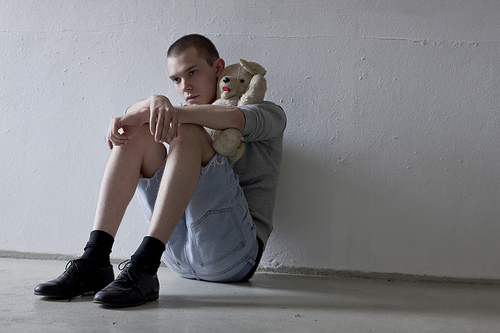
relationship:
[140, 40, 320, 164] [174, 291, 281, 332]
boy on cement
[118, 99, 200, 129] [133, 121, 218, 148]
arms on knees